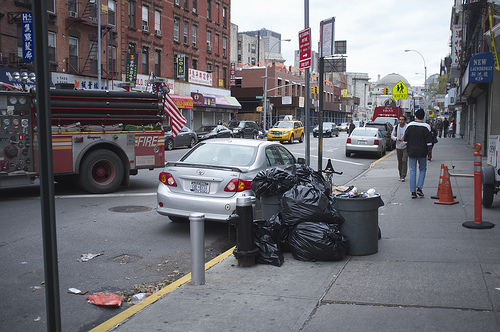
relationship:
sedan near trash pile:
[157, 139, 310, 226] [251, 162, 348, 266]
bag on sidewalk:
[288, 220, 348, 262] [92, 135, 499, 331]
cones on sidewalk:
[432, 167, 465, 216] [92, 135, 499, 331]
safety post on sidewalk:
[462, 142, 495, 229] [92, 135, 499, 331]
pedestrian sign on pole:
[391, 80, 408, 99] [397, 99, 400, 123]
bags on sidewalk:
[251, 162, 348, 266] [92, 135, 499, 331]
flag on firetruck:
[161, 91, 187, 141] [0, 80, 165, 196]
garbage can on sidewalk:
[331, 191, 385, 257] [92, 135, 499, 331]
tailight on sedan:
[159, 172, 177, 187] [157, 139, 310, 226]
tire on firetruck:
[77, 149, 124, 193] [0, 80, 165, 196]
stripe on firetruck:
[52, 137, 74, 151] [0, 80, 165, 196]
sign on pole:
[298, 26, 311, 70] [303, 0, 310, 167]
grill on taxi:
[269, 129, 288, 135] [266, 114, 306, 143]